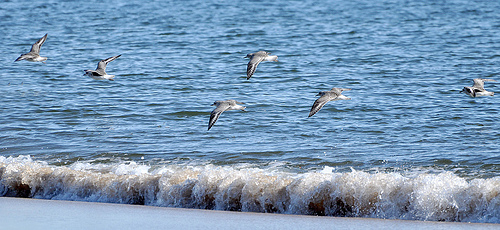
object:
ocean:
[0, 1, 500, 228]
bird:
[13, 29, 51, 69]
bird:
[82, 52, 128, 85]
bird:
[241, 46, 277, 82]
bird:
[203, 95, 248, 136]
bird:
[303, 81, 351, 118]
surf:
[0, 153, 499, 222]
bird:
[447, 74, 498, 106]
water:
[2, 0, 497, 189]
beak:
[458, 89, 463, 94]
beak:
[311, 92, 319, 97]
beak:
[241, 55, 248, 60]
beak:
[209, 102, 214, 108]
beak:
[81, 68, 88, 73]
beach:
[0, 195, 500, 230]